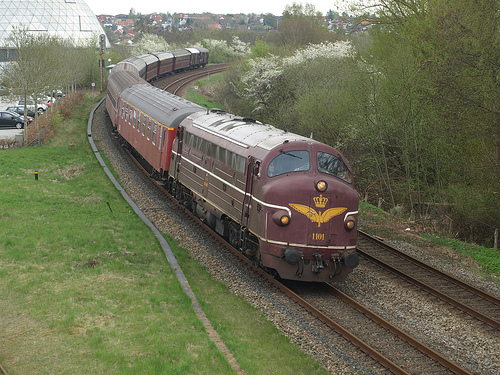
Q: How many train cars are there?
A: Nine.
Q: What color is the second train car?
A: Red.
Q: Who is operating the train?
A: The conductor.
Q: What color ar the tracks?
A: Brown.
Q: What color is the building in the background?
A: White.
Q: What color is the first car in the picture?
A: Black.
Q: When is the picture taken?
A: Daytime.